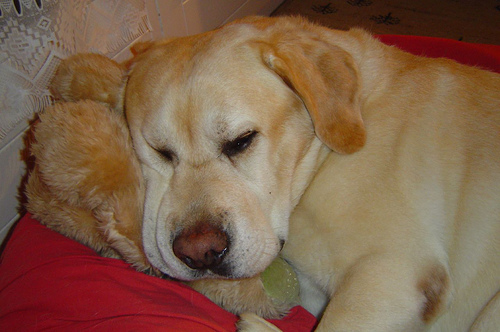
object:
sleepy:
[132, 76, 308, 281]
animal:
[123, 14, 499, 332]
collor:
[0, 0, 500, 332]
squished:
[23, 114, 304, 317]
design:
[0, 0, 67, 80]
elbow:
[342, 229, 453, 320]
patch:
[417, 263, 450, 324]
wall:
[0, 0, 287, 239]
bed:
[0, 210, 318, 332]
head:
[125, 16, 368, 280]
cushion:
[0, 212, 320, 332]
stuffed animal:
[20, 51, 301, 320]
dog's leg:
[294, 247, 453, 332]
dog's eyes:
[147, 129, 257, 162]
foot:
[261, 256, 300, 307]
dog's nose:
[171, 220, 231, 270]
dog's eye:
[149, 144, 176, 164]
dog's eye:
[222, 129, 258, 157]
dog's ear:
[260, 34, 368, 155]